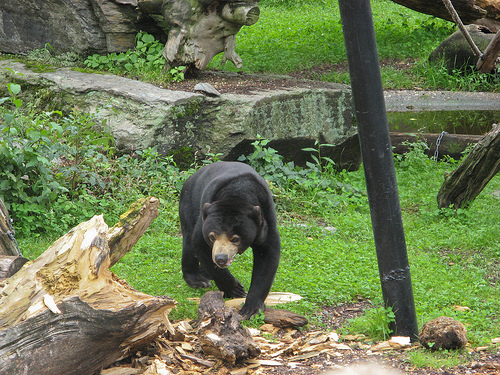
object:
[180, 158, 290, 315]
bear cub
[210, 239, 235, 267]
snout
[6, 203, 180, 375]
log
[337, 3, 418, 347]
pillar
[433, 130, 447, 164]
chain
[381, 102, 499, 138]
water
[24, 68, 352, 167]
rock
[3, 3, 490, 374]
enclosure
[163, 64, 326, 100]
soil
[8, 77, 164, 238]
vegetation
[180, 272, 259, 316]
paws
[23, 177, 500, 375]
grass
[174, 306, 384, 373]
wood chips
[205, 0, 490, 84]
grass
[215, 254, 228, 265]
nose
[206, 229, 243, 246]
eyes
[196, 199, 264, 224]
ears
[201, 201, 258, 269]
head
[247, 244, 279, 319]
leg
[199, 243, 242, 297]
leg